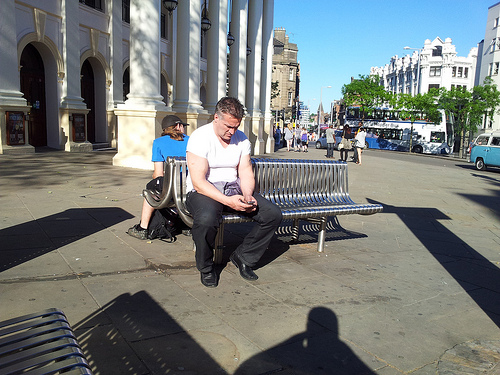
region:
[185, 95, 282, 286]
Man sitting on metal bench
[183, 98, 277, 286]
Man wearing white shirt and black pants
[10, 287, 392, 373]
Shadow of bench and a person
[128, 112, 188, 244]
Lady with black hat and blue shirt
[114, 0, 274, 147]
Tall columns in front of building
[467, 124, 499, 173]
Blue and white van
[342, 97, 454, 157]
Double decker white bus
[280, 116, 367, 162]
People walking down the street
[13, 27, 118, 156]
Arched doorways in front of building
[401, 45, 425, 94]
Street light on a pole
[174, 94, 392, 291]
A MAN SITTING ON A BENCH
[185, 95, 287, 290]
A MAN LOOKING AT HIS CELL PHONE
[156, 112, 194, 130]
A BLACK HAT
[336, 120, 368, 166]
PEOPLE WALKING IN THE BACKGROUND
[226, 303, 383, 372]
A SHADOW ON THE GROUND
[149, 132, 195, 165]
A BLUE TEE SHIRT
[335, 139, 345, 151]
A WHITE PURSE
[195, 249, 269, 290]
PAIR OF MEN'S SHOES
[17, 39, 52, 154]
A BROWN WOODEN DOOR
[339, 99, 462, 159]
A DOUBLE DECKER BUS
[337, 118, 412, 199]
people are walking on the pavement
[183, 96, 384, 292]
a man is sitting on the bench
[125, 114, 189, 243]
a person with black cap is sitting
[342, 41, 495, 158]
there are trees with green leaves in front of the building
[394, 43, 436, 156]
a tall street lamp standing behind the trees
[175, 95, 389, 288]
there is only one guy sitting in the bench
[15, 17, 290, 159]
arch shaped entrances beside the pillars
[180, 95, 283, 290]
the man is looking into his mobile phone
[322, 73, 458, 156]
a bus is moving behind the trees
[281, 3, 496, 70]
the sky is so clear without any clouds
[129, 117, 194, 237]
person in blue shirt and black cap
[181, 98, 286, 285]
man sitting down looking at cell phone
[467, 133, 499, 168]
blue and white Volkswagon bus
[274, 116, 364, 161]
group of people near building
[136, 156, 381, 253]
grey metal benches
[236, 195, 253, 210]
cell phone in man's hands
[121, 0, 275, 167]
tall white stucco pillars in front of building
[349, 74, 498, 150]
green trees lining the street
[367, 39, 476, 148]
white Gothic style stucco building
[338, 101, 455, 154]
double decker bus on street